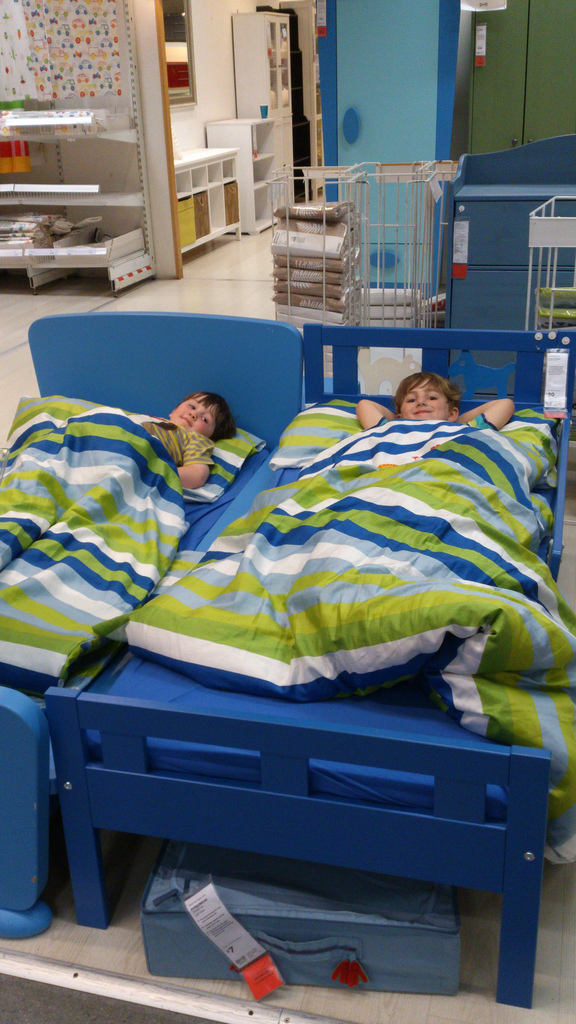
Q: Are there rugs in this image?
A: No, there are no rugs.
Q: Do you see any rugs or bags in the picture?
A: No, there are no rugs or bags.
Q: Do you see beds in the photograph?
A: Yes, there is a bed.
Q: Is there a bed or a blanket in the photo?
A: Yes, there is a bed.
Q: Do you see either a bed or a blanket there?
A: Yes, there is a bed.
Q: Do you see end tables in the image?
A: No, there are no end tables.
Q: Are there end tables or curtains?
A: No, there are no end tables or curtains.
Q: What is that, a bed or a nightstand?
A: That is a bed.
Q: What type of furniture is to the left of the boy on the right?
A: The piece of furniture is a bed.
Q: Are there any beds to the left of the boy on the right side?
A: Yes, there is a bed to the left of the boy.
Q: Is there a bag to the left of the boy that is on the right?
A: No, there is a bed to the left of the boy.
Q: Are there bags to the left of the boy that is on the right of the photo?
A: No, there is a bed to the left of the boy.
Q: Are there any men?
A: No, there are no men.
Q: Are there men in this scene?
A: No, there are no men.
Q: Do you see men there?
A: No, there are no men.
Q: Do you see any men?
A: No, there are no men.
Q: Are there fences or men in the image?
A: No, there are no men or fences.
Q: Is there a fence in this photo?
A: No, there are no fences.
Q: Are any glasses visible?
A: No, there are no glasses.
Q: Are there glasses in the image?
A: No, there are no glasses.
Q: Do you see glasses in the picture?
A: No, there are no glasses.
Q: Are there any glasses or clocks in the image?
A: No, there are no glasses or clocks.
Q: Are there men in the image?
A: No, there are no men.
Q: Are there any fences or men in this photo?
A: No, there are no men or fences.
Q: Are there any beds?
A: Yes, there is a bed.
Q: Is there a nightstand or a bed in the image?
A: Yes, there is a bed.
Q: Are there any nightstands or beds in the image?
A: Yes, there is a bed.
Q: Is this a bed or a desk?
A: This is a bed.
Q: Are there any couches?
A: No, there are no couches.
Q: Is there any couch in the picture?
A: No, there are no couches.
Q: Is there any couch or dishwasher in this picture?
A: No, there are no couches or dishwashers.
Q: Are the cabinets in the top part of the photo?
A: Yes, the cabinets are in the top of the image.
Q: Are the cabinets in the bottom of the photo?
A: No, the cabinets are in the top of the image.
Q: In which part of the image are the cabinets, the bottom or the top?
A: The cabinets are in the top of the image.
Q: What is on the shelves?
A: The cabinets are on the shelves.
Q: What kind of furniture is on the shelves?
A: The pieces of furniture are cabinets.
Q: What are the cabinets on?
A: The cabinets are on the shelves.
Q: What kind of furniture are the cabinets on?
A: The cabinets are on the shelves.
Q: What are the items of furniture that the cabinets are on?
A: The pieces of furniture are shelves.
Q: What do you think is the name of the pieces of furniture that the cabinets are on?
A: The pieces of furniture are shelves.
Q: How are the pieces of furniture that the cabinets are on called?
A: The pieces of furniture are shelves.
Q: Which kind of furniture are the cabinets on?
A: The cabinets are on the shelves.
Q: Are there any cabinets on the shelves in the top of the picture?
A: Yes, there are cabinets on the shelves.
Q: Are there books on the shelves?
A: No, there are cabinets on the shelves.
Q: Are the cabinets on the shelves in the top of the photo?
A: Yes, the cabinets are on the shelves.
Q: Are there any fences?
A: No, there are no fences.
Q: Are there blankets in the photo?
A: Yes, there is a blanket.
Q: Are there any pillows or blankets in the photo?
A: Yes, there is a blanket.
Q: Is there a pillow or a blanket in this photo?
A: Yes, there is a blanket.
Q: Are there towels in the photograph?
A: No, there are no towels.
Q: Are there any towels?
A: No, there are no towels.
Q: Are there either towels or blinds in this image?
A: No, there are no towels or blinds.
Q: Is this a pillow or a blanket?
A: This is a blanket.